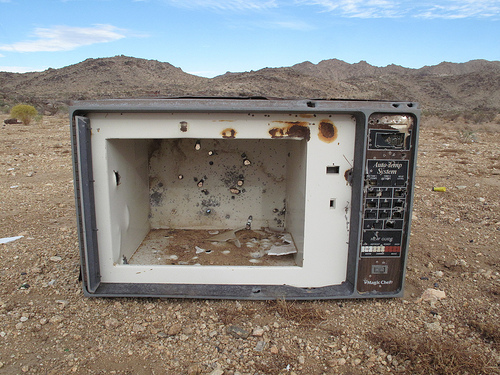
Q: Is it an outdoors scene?
A: Yes, it is outdoors.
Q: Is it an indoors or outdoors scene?
A: It is outdoors.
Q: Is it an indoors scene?
A: No, it is outdoors.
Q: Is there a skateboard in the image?
A: No, there are no skateboards.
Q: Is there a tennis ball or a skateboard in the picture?
A: No, there are no skateboards or tennis balls.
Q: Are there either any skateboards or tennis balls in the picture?
A: No, there are no skateboards or tennis balls.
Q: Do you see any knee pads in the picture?
A: No, there are no knee pads.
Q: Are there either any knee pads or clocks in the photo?
A: No, there are no knee pads or clocks.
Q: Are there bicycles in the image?
A: No, there are no bicycles.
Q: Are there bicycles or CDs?
A: No, there are no bicycles or cds.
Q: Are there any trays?
A: No, there are no trays.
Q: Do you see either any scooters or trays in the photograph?
A: No, there are no trays or scooters.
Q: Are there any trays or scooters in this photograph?
A: No, there are no trays or scooters.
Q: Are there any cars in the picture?
A: No, there are no cars.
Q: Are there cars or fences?
A: No, there are no cars or fences.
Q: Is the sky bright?
A: Yes, the sky is bright.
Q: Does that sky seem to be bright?
A: Yes, the sky is bright.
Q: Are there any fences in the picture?
A: No, there are no fences.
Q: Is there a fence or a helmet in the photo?
A: No, there are no fences or helmets.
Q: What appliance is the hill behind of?
A: The hill is behind the microwave.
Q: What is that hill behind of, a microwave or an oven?
A: The hill is behind a microwave.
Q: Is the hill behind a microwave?
A: Yes, the hill is behind a microwave.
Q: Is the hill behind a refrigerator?
A: No, the hill is behind a microwave.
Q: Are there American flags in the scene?
A: No, there are no American flags.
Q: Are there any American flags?
A: No, there are no American flags.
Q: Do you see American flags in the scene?
A: No, there are no American flags.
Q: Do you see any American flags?
A: No, there are no American flags.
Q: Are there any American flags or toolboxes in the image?
A: No, there are no American flags or toolboxes.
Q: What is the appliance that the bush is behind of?
A: The appliance is a microwave.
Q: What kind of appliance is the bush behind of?
A: The bush is behind the microwave.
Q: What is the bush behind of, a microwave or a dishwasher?
A: The bush is behind a microwave.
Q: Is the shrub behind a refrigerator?
A: No, the shrub is behind a microwave.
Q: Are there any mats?
A: No, there are no mats.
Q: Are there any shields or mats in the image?
A: No, there are no mats or shields.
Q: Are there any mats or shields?
A: No, there are no mats or shields.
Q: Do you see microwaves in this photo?
A: Yes, there is a microwave.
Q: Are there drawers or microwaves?
A: Yes, there is a microwave.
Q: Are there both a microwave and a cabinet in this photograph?
A: No, there is a microwave but no cabinets.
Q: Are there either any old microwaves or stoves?
A: Yes, there is an old microwave.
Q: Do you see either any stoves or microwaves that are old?
A: Yes, the microwave is old.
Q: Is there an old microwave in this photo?
A: Yes, there is an old microwave.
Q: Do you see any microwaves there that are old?
A: Yes, there is a microwave that is old.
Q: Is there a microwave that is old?
A: Yes, there is a microwave that is old.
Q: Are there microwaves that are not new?
A: Yes, there is a old microwave.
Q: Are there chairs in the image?
A: No, there are no chairs.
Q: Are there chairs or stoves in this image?
A: No, there are no chairs or stoves.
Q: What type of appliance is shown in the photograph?
A: The appliance is a microwave.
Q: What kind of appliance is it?
A: The appliance is a microwave.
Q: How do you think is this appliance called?
A: This is a microwave.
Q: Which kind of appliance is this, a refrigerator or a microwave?
A: This is a microwave.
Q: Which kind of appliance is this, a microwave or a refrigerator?
A: This is a microwave.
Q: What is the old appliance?
A: The appliance is a microwave.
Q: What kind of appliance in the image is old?
A: The appliance is a microwave.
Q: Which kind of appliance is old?
A: The appliance is a microwave.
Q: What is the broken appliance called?
A: The appliance is a microwave.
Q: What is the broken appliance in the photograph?
A: The appliance is a microwave.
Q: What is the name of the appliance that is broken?
A: The appliance is a microwave.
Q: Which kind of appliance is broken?
A: The appliance is a microwave.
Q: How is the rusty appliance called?
A: The appliance is a microwave.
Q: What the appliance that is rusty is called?
A: The appliance is a microwave.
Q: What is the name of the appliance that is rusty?
A: The appliance is a microwave.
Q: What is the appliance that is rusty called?
A: The appliance is a microwave.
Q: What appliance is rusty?
A: The appliance is a microwave.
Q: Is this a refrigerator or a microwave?
A: This is a microwave.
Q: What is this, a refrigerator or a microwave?
A: This is a microwave.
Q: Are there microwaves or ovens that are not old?
A: No, there is a microwave but it is old.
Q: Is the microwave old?
A: Yes, the microwave is old.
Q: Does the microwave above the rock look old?
A: Yes, the microwave is old.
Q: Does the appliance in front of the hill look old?
A: Yes, the microwave is old.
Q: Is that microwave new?
A: No, the microwave is old.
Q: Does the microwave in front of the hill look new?
A: No, the microwave is old.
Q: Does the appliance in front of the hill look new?
A: No, the microwave is old.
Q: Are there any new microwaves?
A: No, there is a microwave but it is old.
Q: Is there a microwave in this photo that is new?
A: No, there is a microwave but it is old.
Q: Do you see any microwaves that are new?
A: No, there is a microwave but it is old.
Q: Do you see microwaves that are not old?
A: No, there is a microwave but it is old.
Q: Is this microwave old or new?
A: The microwave is old.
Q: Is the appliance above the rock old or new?
A: The microwave is old.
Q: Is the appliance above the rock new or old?
A: The microwave is old.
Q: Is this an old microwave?
A: Yes, this is an old microwave.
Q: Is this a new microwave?
A: No, this is an old microwave.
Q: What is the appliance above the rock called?
A: The appliance is a microwave.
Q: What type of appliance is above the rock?
A: The appliance is a microwave.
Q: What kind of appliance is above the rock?
A: The appliance is a microwave.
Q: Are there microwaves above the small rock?
A: Yes, there is a microwave above the rock.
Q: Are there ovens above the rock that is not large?
A: No, there is a microwave above the rock.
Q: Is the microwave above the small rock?
A: Yes, the microwave is above the rock.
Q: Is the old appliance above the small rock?
A: Yes, the microwave is above the rock.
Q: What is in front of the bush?
A: The microwave is in front of the shrub.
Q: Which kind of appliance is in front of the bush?
A: The appliance is a microwave.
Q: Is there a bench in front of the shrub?
A: No, there is a microwave in front of the shrub.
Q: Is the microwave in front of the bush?
A: Yes, the microwave is in front of the bush.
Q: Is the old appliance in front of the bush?
A: Yes, the microwave is in front of the bush.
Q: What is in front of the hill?
A: The microwave is in front of the hill.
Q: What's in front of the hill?
A: The microwave is in front of the hill.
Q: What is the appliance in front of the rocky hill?
A: The appliance is a microwave.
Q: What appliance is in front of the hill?
A: The appliance is a microwave.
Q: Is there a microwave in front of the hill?
A: Yes, there is a microwave in front of the hill.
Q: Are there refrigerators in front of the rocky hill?
A: No, there is a microwave in front of the hill.